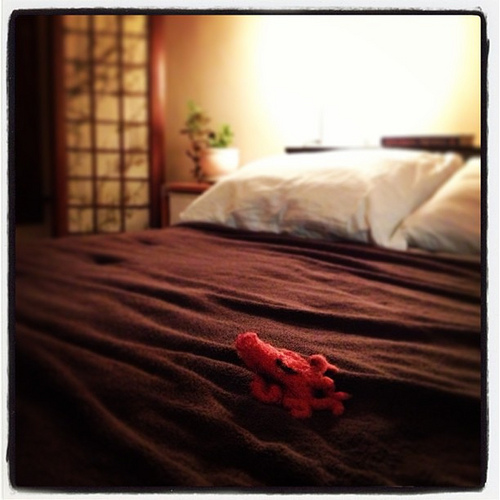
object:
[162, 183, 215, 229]
table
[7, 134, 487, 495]
bed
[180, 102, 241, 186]
plant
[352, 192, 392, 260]
wrinkle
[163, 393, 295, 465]
wrinkle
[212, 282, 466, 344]
wrinkle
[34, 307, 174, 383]
wrinkle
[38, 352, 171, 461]
wrinkle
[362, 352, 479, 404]
wrinkle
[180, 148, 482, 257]
pillows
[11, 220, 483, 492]
covers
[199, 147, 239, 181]
white pot